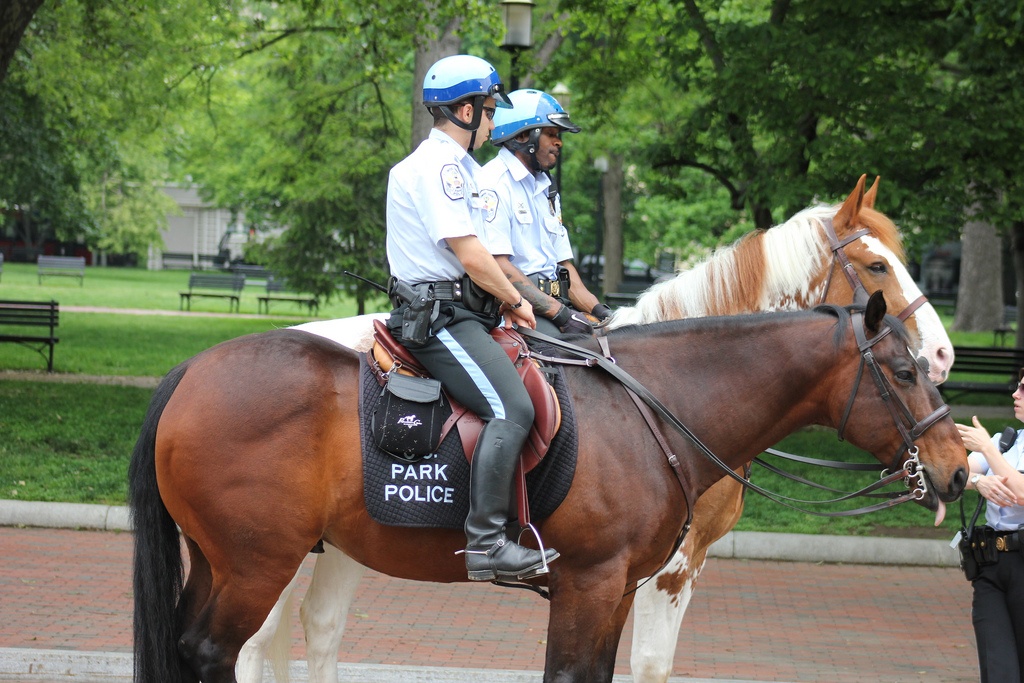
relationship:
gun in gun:
[390, 274, 435, 347] [391, 281, 437, 347]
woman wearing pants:
[958, 375, 1019, 680] [960, 530, 1021, 678]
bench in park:
[5, 296, 57, 370] [5, 5, 1019, 531]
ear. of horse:
[832, 171, 865, 230] [236, 156, 950, 679]